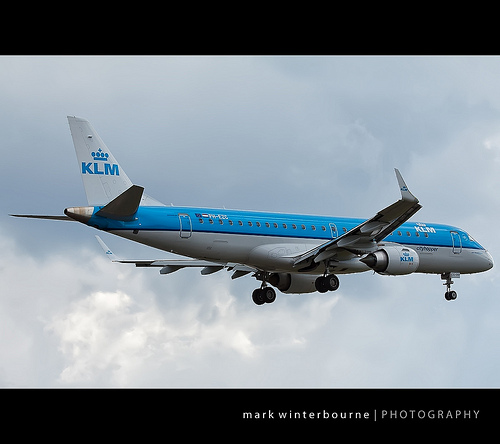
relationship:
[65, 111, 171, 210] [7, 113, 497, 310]
tail on plane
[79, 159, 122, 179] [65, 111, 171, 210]
klm on tail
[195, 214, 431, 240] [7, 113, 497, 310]
windows on plane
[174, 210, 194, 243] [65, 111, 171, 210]
door near tail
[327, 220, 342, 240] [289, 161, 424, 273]
door near wing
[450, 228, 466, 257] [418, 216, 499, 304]
door near front of plane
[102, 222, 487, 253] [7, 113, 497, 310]
stripe on plane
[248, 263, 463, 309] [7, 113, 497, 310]
landing gear on jet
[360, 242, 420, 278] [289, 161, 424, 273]
engine on wing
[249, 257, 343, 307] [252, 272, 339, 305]
back landing gear has wheels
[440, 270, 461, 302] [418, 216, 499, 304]
landing gear on front of plane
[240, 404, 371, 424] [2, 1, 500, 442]
watermark on photo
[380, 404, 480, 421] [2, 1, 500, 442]
photography on photo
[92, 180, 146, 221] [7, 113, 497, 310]
back wing on plane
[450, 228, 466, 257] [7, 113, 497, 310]
front door on plane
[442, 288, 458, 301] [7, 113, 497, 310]
front wheels on plane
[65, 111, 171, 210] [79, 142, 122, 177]
tail has logo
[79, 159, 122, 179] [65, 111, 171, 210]
writing on tail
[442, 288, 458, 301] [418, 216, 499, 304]
wheels on front of plane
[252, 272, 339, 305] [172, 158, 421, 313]
wheels in middle of plane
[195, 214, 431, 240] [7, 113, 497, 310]
windows along airplane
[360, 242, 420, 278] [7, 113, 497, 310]
engine of airplane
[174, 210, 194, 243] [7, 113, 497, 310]
back door of airplane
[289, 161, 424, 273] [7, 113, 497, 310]
wing of airplane